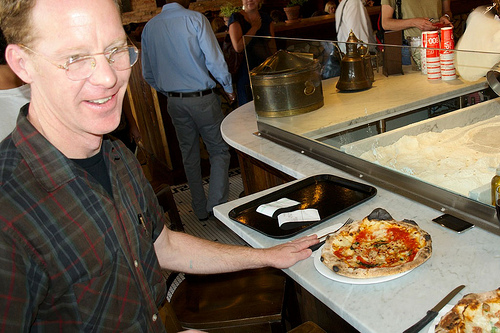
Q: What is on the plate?
A: PIzza.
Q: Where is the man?
A: Restaurant.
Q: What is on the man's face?
A: Glasses.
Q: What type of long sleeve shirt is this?
A: A blue long sleeve shirt.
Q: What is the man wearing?
A: A pair of grey pants.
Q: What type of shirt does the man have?
A: A blue and red shirt.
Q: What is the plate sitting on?
A: The plate is on the grey counter.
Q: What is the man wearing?
A: The man is wearing glasses.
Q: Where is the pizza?
A: The pizza in on the countertop.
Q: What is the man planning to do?
A: The man is going to eat.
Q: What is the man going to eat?
A: The man is going to eat pizza.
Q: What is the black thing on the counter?
A: Tray.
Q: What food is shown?
A: Pizza.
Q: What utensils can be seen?
A: Fork and knives.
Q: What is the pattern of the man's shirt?
A: Plaid.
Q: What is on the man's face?
A: Glasses.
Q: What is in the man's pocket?
A: Pen.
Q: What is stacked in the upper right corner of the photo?
A: Cups.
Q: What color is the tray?
A: Black.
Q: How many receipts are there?
A: Two.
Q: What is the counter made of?
A: Marble.